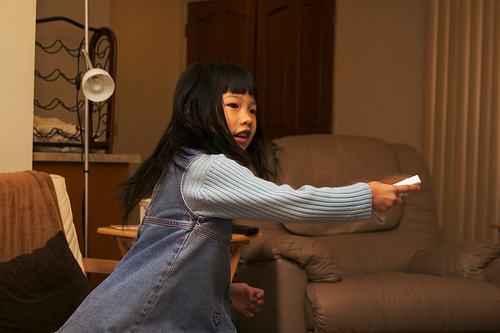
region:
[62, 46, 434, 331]
girl playing Wii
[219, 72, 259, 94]
bangs on the forehead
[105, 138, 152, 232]
hair is blowing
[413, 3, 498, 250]
white curtains on the window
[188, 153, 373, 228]
arm is outstretched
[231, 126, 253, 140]
mouth is open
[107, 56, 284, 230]
long dark hair on the head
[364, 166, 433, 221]
white Wii controller in the hand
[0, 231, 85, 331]
dark brown pillow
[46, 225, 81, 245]
corner of the pillow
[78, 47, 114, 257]
Flexible plain model standing lamp.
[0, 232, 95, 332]
Brown velvet sofa pillow.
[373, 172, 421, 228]
White hand held game controller.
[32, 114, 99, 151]
White linen on counter top.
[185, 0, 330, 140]
Wooden french double doors.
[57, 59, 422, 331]
Young Asian girl playing with a Wii.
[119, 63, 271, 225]
Long black hair on little girl.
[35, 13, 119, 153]
Wooden wine rack on counter top.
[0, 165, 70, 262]
Light brown blanket on couch.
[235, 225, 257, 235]
Black TV remote on table top.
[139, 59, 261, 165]
the hair is black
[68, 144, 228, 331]
the dress is jeans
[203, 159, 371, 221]
the sweater is woolen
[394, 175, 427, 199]
the girl is holding a cloth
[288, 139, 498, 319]
the chair is brown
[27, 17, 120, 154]
the shelf is metallic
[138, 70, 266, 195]
the hair is long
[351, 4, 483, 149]
the wall is brown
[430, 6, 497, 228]
the curtain is brown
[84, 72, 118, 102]
the bulb holder is white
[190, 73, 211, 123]
this is the hair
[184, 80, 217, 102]
the hair is black in colour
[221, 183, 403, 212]
this is the hand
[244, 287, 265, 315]
these are the fingers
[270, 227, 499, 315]
this is the chair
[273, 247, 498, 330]
the chair is brown in colour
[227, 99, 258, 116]
these are the eyes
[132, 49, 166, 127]
this is the wall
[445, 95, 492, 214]
this is the curtain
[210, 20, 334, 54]
this is the door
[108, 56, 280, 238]
Head with long straight black hair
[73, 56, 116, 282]
White lampshade on a metal stand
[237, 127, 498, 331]
Grey single sitter couch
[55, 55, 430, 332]
Young girl with hand straightened out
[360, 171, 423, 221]
Hand holding a white object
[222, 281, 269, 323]
Hand folded into a claw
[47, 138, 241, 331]
Light blue jeans dress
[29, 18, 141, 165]
Small rack on top of a stand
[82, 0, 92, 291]
Long thin silver colored metal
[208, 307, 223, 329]
Small badge on the dress